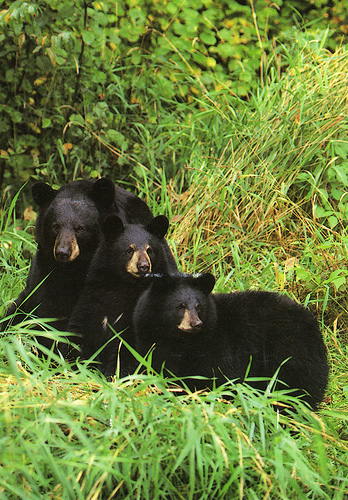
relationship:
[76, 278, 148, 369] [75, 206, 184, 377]
stomach of a bear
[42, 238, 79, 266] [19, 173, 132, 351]
nose of bear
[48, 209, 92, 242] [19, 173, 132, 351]
eye of bear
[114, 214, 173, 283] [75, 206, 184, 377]
face of bear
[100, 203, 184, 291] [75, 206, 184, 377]
head of bear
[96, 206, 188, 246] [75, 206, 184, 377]
ear of bear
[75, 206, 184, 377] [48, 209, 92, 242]
bear has eye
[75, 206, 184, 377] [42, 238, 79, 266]
bear has nose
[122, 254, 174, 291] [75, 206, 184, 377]
nose of bear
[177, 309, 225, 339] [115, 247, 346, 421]
nose of bear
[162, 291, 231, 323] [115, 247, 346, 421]
eye of bear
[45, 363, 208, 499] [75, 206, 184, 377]
grass in front of bear